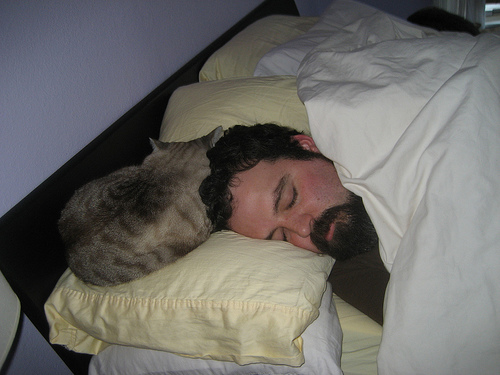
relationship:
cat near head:
[58, 122, 229, 290] [198, 117, 383, 260]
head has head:
[198, 118, 378, 263] [198, 117, 383, 260]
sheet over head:
[294, 7, 499, 374] [198, 118, 378, 263]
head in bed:
[198, 118, 378, 263] [0, 0, 499, 374]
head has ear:
[198, 118, 378, 263] [284, 128, 323, 155]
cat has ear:
[58, 122, 229, 290] [204, 121, 227, 149]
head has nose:
[198, 118, 378, 263] [276, 211, 316, 237]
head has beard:
[198, 118, 378, 263] [309, 189, 379, 262]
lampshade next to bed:
[1, 263, 25, 374] [0, 0, 499, 374]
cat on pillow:
[58, 122, 229, 290] [41, 72, 338, 370]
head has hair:
[198, 118, 378, 263] [199, 121, 323, 237]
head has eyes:
[198, 118, 378, 263] [265, 170, 300, 246]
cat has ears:
[58, 122, 229, 290] [145, 121, 226, 157]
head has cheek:
[198, 118, 378, 263] [300, 159, 346, 209]